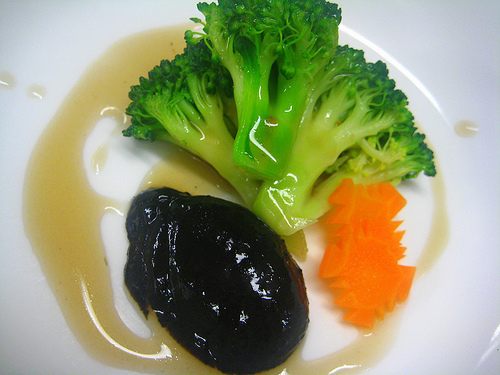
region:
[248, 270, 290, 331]
part of a fruit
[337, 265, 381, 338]
part of a carrot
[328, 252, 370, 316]
part of a carrot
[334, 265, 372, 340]
edge of a carrot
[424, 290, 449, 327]
part of a plate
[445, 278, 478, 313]
edge of a dish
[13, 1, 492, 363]
a plain white plate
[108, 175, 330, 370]
a black mound of food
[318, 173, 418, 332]
a bright orange carrot slice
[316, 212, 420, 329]
a decoratively cut vegetable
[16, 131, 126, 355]
a light brown sauce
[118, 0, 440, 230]
a few pieces of broccoli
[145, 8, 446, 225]
a cooked green vegetable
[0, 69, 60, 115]
some droplets of sauce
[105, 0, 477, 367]
a simple vegetarian dish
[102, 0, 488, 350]
vegetables on a plate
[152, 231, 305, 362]
a black shell on a plate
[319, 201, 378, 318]
a fancy slices carrot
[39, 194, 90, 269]
brown liquid on the plate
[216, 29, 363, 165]
a mound of green broccoli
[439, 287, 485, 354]
a white ceramic plate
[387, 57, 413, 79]
light reflected on the plate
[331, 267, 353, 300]
the serrated edge of the carrot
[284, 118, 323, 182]
the crunchy stalk on the broccoli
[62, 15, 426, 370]
a vegetarian meal on a plate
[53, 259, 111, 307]
brown water on the plate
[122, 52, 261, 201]
a piece of green cooked brocolli with sauce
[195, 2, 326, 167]
a piece of green cooked brocolli with sauce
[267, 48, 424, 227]
a piece of green cooked brocolli with sauce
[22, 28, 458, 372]
brown opaque sauce on a plate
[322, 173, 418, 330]
a piece of orange carrot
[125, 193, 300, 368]
a blob of deep black food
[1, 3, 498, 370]
a white plate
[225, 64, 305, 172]
the stem of a piece of brocolli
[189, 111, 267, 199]
the stem of a piece of brocolli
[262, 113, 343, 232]
the stem of a piece of brocolli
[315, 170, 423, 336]
carved carrot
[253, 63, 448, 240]
broccoli floret w/ yellowy brown sauce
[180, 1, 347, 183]
middle floret is darker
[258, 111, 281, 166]
a large spice piece+a tiny spice piece, both from the sauce, @ end of mid-floret's groove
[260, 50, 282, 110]
an open space between a bright kelly green pair of siamese twin florets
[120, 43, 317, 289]
the third, & bottom floret is the longest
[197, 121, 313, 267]
itdriplets of, & reflections of light in, sauce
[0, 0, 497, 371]
plate or dish is white, not photographed in full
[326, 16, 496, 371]
reflections of light pieces on the plate in places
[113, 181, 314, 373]
a purple lump